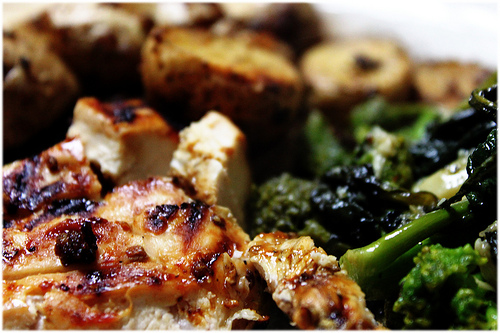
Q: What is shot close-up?
A: Food.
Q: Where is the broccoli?
A: On the right.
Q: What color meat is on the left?
A: White.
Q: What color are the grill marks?
A: Brown.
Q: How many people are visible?
A: Zero.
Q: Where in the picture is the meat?
A: On the left.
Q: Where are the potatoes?
A: In the back.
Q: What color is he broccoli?
A: Green.